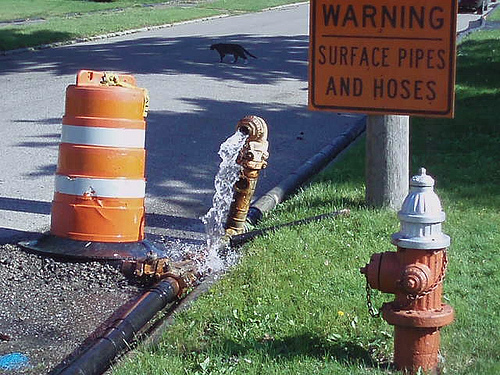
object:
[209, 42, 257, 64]
black cat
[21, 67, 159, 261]
cone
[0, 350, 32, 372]
painted dot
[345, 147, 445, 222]
ground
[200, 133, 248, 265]
water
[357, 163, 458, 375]
hydrant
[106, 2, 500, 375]
grass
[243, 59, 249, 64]
white paws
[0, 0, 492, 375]
road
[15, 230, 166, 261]
rubber base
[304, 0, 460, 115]
orange sign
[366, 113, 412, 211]
post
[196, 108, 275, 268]
water leak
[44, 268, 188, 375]
surface pipe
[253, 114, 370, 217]
surface pipe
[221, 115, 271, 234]
pipe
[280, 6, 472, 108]
sign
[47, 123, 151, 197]
stripes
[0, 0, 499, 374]
area